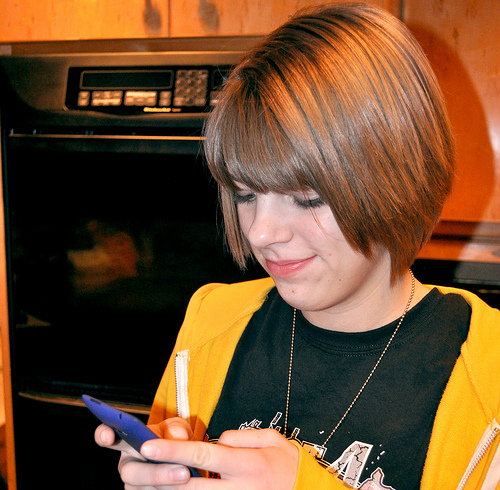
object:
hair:
[202, 1, 461, 289]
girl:
[94, 0, 498, 490]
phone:
[80, 393, 202, 477]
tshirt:
[194, 284, 471, 490]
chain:
[282, 266, 414, 458]